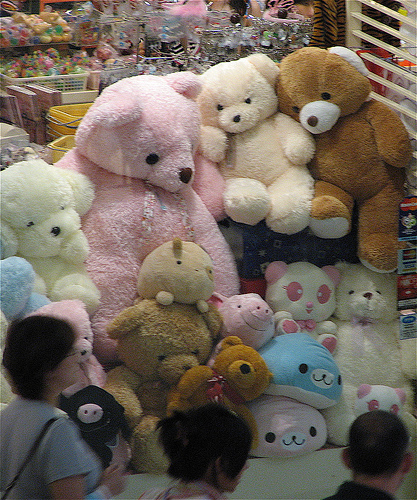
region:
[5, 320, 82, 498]
a lady looking at the teddy bears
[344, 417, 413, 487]
a man looking at the teddy bears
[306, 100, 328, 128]
the nose of a teddy bear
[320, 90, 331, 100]
the eye of a teddy bear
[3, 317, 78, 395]
the head of a lady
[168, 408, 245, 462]
the hair of a person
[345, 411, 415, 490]
the head of a man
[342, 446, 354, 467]
the ear of a man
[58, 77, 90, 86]
a plastic tray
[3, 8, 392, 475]
novelty store with stuffed toys and candy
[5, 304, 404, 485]
people observing the stuffed toys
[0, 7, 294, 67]
candy in the store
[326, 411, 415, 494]
individual on end looking at toy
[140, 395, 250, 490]
woman in middle looking at toy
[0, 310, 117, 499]
woman on end looking at toy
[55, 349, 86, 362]
glasses on woman's face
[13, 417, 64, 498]
strap behind woman's back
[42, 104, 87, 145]
baskets in the back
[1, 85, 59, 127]
books in the back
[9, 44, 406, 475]
a store-window display of many stuffed animals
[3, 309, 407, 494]
three people walking by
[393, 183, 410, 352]
informational stickers stuck to the window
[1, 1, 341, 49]
small items for sale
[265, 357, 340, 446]
two smiling toy faces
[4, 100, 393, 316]
toys bunched together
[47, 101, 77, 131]
yellow plastic stacked baskets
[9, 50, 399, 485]
people walk past a display of toys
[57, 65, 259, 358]
A giant pink teddy bear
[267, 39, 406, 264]
A big brown/white teddy bear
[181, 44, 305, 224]
A big white teddy bear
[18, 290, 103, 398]
A small pink teddy bear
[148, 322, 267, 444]
A small brown teddy bear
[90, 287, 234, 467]
A big brown teddy bear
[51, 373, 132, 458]
A black pig doll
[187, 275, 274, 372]
A pink pig doll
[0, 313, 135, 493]
A woman looking at some stuffed animals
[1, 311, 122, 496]
A woman wearing a blue shirt